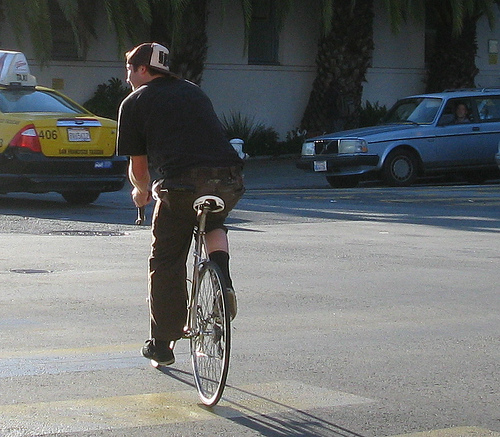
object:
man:
[452, 102, 471, 124]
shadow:
[157, 363, 365, 437]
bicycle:
[132, 166, 236, 407]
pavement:
[1, 185, 499, 436]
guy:
[111, 40, 248, 369]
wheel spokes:
[190, 274, 225, 399]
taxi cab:
[0, 45, 130, 207]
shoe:
[140, 339, 177, 368]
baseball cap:
[123, 41, 185, 79]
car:
[295, 85, 500, 188]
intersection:
[1, 195, 499, 437]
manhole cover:
[47, 227, 126, 239]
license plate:
[66, 124, 92, 143]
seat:
[191, 193, 225, 215]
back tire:
[189, 256, 234, 409]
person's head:
[119, 38, 175, 92]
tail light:
[12, 122, 43, 155]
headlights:
[301, 138, 315, 157]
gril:
[310, 140, 340, 154]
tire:
[384, 151, 414, 185]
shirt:
[111, 75, 242, 169]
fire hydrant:
[228, 136, 250, 181]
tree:
[304, 1, 378, 135]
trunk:
[300, 0, 377, 132]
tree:
[106, 0, 209, 88]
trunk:
[152, 1, 209, 87]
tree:
[420, 0, 477, 96]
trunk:
[423, 1, 481, 93]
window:
[46, 2, 86, 60]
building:
[2, 1, 499, 141]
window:
[246, 0, 281, 67]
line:
[0, 374, 377, 437]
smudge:
[120, 393, 209, 424]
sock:
[208, 248, 234, 287]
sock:
[153, 337, 169, 350]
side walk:
[123, 156, 328, 193]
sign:
[0, 46, 37, 89]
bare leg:
[204, 227, 230, 256]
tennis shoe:
[215, 283, 239, 322]